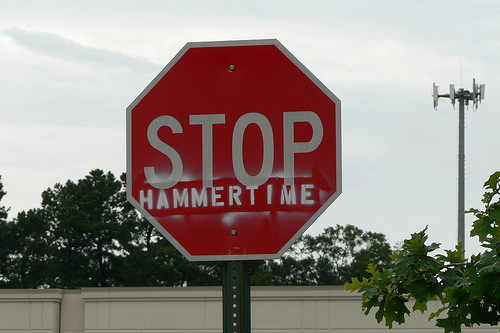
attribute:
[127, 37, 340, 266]
stop sign — white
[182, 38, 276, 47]
border — white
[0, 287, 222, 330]
fence — color white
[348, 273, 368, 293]
leaf — green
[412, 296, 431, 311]
leaf — green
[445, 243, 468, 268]
leaf — green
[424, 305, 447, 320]
leaf — green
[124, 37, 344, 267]
sign — red, white, octagon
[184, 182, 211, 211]
letter — white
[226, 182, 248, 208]
letter — white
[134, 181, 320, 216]
paint — white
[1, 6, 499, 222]
clouds — white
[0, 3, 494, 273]
sky — blue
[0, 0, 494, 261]
clouds — white